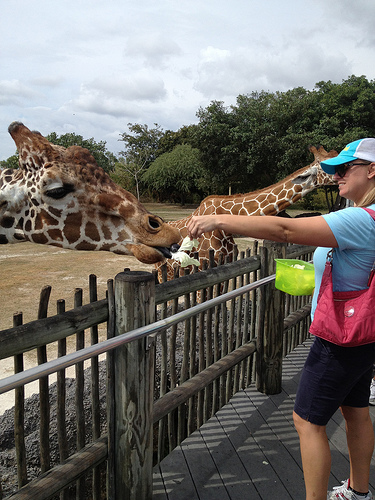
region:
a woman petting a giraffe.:
[0, 117, 177, 287]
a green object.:
[263, 232, 348, 302]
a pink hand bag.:
[304, 212, 373, 352]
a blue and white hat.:
[315, 144, 371, 180]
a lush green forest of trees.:
[0, 77, 373, 199]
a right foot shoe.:
[325, 476, 373, 498]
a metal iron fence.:
[0, 243, 284, 496]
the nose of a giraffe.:
[128, 197, 190, 275]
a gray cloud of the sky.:
[0, 0, 370, 152]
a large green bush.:
[131, 141, 210, 208]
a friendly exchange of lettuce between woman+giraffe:
[133, 207, 263, 280]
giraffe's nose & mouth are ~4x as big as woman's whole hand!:
[136, 199, 216, 280]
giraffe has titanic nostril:
[140, 210, 163, 233]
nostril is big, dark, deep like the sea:
[145, 212, 163, 233]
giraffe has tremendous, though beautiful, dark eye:
[38, 177, 78, 204]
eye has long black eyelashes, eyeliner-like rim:
[39, 180, 76, 203]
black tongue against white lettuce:
[150, 231, 203, 268]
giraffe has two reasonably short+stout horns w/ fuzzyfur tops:
[7, 119, 57, 164]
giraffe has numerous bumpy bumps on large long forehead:
[59, 140, 116, 190]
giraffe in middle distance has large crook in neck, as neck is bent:
[189, 188, 260, 223]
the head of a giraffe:
[0, 118, 186, 266]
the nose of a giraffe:
[141, 209, 166, 235]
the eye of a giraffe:
[35, 176, 82, 207]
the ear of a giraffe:
[288, 165, 318, 189]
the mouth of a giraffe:
[134, 233, 181, 260]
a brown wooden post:
[103, 265, 158, 499]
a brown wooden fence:
[0, 223, 325, 498]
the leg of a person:
[283, 333, 347, 497]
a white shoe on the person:
[325, 476, 374, 499]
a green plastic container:
[272, 254, 319, 300]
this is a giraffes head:
[0, 132, 175, 255]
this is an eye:
[43, 181, 74, 199]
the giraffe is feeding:
[143, 235, 182, 262]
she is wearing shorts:
[298, 347, 367, 412]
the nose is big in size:
[143, 216, 164, 228]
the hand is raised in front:
[189, 208, 316, 239]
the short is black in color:
[309, 355, 357, 397]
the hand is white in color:
[241, 218, 271, 230]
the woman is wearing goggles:
[334, 162, 349, 175]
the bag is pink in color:
[319, 287, 367, 336]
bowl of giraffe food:
[271, 256, 313, 294]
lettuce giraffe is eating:
[168, 231, 198, 269]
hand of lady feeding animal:
[171, 210, 225, 270]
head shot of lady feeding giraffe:
[317, 135, 369, 198]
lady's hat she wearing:
[316, 135, 369, 169]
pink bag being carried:
[303, 203, 369, 345]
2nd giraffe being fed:
[225, 141, 330, 232]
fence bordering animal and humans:
[47, 273, 246, 492]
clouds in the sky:
[33, 10, 304, 81]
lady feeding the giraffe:
[5, 120, 371, 266]